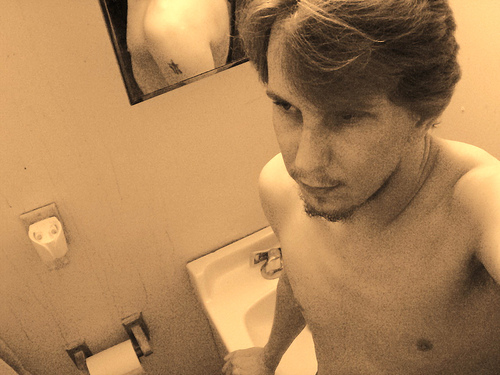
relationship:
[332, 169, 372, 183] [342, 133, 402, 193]
part on cheek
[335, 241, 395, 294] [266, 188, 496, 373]
part on chest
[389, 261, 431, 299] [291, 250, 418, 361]
part of chest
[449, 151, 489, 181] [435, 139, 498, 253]
part of shoulder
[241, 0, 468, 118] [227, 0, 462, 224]
hair on head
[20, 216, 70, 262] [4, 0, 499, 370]
dispenser on wall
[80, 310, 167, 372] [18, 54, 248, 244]
holder on wall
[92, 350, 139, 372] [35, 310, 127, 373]
roll of toilet paper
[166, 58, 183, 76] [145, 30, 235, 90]
tattoo on arm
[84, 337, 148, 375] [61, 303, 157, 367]
toilet paper on holder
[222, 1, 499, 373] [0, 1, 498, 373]
man in bathroom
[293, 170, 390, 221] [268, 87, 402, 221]
beard on face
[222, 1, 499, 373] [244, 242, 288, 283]
man next to faucet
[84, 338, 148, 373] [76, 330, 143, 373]
toilet paper on roll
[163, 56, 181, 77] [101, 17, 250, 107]
tattoo in mirror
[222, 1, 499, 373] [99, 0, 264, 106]
man next to mirror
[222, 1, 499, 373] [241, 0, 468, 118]
man has hair